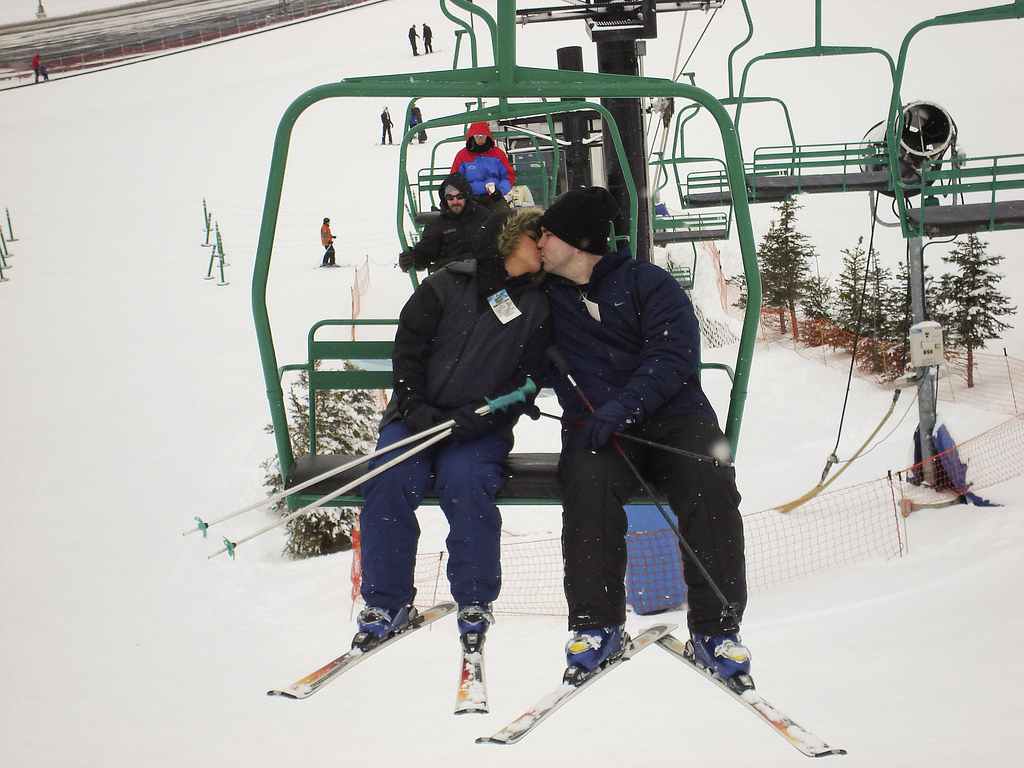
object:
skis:
[472, 619, 680, 765]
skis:
[452, 602, 493, 716]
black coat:
[395, 171, 493, 273]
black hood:
[438, 169, 472, 217]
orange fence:
[348, 213, 1024, 619]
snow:
[0, 0, 1022, 766]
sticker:
[487, 288, 524, 325]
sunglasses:
[445, 191, 467, 200]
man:
[399, 172, 494, 276]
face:
[444, 184, 466, 215]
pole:
[217, 243, 225, 283]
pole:
[206, 245, 216, 278]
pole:
[217, 231, 225, 264]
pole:
[206, 213, 212, 245]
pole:
[4, 206, 17, 241]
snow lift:
[247, 0, 789, 437]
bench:
[269, 319, 744, 513]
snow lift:
[245, 0, 762, 512]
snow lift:
[727, 0, 901, 204]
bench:
[744, 141, 897, 204]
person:
[320, 217, 341, 268]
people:
[380, 106, 395, 146]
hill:
[0, 0, 1024, 768]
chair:
[897, 151, 1021, 238]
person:
[406, 103, 427, 145]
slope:
[245, 92, 320, 302]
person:
[450, 121, 516, 223]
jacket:
[448, 121, 515, 198]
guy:
[529, 185, 750, 682]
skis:
[637, 625, 849, 759]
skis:
[264, 600, 463, 702]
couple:
[250, 186, 850, 764]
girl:
[354, 187, 555, 642]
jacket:
[378, 206, 554, 435]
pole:
[901, 101, 942, 491]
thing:
[864, 98, 957, 199]